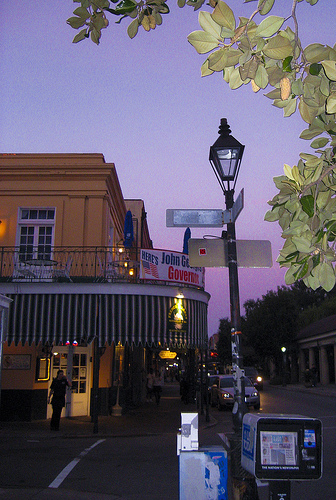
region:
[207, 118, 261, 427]
black metal street light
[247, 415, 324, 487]
black and silver newspaper stand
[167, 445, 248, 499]
blue metal newspaper stand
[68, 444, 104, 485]
black faded line on street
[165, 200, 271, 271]
two silver street signs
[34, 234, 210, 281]
balcony roof top area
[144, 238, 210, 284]
running for governer sign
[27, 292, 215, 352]
black and white striped banner storefront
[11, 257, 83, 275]
patio set on balcony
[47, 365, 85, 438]
woman worker walking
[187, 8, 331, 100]
green leaves on a tree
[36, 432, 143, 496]
white lines on the road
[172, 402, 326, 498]
newspaper dispensers on a corner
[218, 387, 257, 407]
headlights on a parked car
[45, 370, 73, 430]
a person in black walking out of a building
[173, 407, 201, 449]
the metal top of a newpaper stand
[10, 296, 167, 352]
a striped valance above a building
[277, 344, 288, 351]
a bright white street light to the right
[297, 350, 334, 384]
concrete pillars on the front of a building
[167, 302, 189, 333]
the green and yellow sign on the front of a building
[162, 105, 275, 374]
black and white light pole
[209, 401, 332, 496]
newspaper stand on corner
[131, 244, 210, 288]
red, white, and blue banner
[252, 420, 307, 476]
newspaper inside paper machine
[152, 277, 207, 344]
light over building sign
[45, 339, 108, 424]
person walking from doorway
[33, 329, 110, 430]
white door with lights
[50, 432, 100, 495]
white line painted on road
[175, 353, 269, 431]
car parked at curb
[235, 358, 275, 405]
headlight of vehicle on road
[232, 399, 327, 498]
coin-operated newspaper dispenser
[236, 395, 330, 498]
USA today newspaper machine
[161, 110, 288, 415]
tall black lamppost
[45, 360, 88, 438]
woman wearing black clothes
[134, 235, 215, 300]
governor campaign sign on a balcony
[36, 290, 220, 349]
green and white awning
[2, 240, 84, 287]
patio table with two chairs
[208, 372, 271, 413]
Volvo car parked on street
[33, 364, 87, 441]
woman standing on a sidwalk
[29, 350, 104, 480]
woman drinking a beverage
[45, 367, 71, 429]
woman walking on sidewalk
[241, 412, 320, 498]
metal newspaper vending machine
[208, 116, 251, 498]
black iron lamp post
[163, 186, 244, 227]
white street name sign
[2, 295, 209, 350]
black and white striped awning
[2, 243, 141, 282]
black iron barrier fence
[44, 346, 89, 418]
white door for restaurant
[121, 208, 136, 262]
blue folded patio umbrella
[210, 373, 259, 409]
car parked by curb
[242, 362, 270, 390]
car driving on street